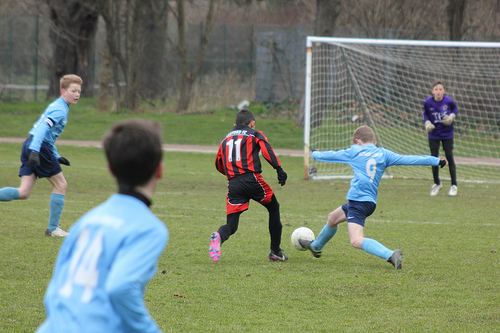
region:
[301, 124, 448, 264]
soccer player on field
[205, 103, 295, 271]
soccer player on field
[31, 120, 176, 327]
soccer player on field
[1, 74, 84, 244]
soccer player on field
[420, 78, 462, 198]
soccer player on field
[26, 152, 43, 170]
warm black cloth gloves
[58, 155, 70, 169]
warm black cloth gloves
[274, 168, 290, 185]
warm black cloth gloves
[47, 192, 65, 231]
long blue soccer socks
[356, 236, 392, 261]
long blue soccer socks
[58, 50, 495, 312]
kids that are playing soccer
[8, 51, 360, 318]
boys playing soccer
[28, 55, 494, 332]
young boys playing soccer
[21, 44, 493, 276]
boys wearing a uniform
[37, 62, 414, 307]
children wearing soccer uniforms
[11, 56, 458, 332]
kids wearing blue soccer uniforms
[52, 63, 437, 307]
boys wearing blue uniform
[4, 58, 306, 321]
boys running in a field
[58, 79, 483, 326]
boys playing on a soccer field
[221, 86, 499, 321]
a boy kicking a ball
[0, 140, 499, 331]
a green grass soccer field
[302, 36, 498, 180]
one of the soccer goals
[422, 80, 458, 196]
a soccer goalie with purple jersey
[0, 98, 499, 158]
an area of green grass in the background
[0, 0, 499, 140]
a wooded area in the background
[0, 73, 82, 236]
a soccer player on the blue team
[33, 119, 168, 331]
a soccer player on the blue team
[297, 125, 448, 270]
a soccer player on the blue team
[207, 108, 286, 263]
a soccer player with striped uniform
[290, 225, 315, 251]
a white soccer ball being kicked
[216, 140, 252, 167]
number on the jersey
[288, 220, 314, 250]
soccer ball on the field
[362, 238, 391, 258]
sock on the calf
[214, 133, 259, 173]
red and black jersey on the player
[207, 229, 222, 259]
cleat on the player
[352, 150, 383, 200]
jersey on the player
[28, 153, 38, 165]
glove on the player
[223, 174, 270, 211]
shorts on the player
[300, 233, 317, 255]
shoe on the player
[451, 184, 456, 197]
shoe on the player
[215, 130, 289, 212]
red and black team uniform of the offensive team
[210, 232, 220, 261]
pink sole of the shoe of red and black team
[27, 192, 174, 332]
sky blue jersey of the team on defense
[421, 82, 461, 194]
goalie stands by the goal in a purple jersey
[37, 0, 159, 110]
section of the bare autumn trees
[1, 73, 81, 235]
player in blue watches the others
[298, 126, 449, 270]
player in blue with number 9 runs toward the ball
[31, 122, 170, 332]
player in blue with number 14 follows from behind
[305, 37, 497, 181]
soccer goal with white bars and netting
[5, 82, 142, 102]
pond in the background behind the trees